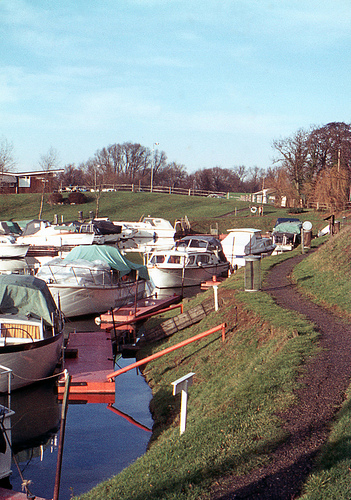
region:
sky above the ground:
[143, 13, 231, 85]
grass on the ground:
[208, 368, 263, 418]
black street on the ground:
[274, 393, 343, 437]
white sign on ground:
[156, 364, 212, 430]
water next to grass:
[93, 436, 121, 453]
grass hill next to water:
[132, 445, 181, 483]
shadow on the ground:
[237, 418, 302, 477]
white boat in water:
[156, 236, 224, 290]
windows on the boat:
[149, 252, 193, 274]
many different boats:
[8, 194, 227, 318]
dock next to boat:
[66, 327, 114, 400]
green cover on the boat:
[58, 238, 151, 292]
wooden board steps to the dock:
[171, 291, 254, 334]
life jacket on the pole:
[246, 200, 262, 215]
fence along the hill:
[113, 175, 346, 215]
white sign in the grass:
[164, 367, 194, 441]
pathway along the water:
[250, 248, 347, 489]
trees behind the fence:
[93, 145, 349, 202]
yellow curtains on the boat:
[7, 313, 43, 340]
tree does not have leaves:
[93, 168, 127, 206]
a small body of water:
[2, 219, 305, 497]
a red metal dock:
[59, 297, 229, 395]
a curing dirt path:
[209, 241, 345, 497]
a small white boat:
[0, 283, 68, 402]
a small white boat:
[41, 244, 148, 311]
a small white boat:
[144, 235, 232, 292]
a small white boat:
[221, 223, 270, 265]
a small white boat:
[113, 210, 174, 236]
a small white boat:
[20, 222, 97, 250]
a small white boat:
[0, 233, 28, 259]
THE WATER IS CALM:
[0, 300, 161, 499]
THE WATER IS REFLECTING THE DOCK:
[24, 337, 150, 472]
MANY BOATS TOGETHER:
[0, 214, 314, 498]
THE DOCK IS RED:
[52, 287, 230, 403]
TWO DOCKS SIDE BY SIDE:
[54, 285, 232, 396]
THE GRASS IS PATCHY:
[2, 191, 350, 498]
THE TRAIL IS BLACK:
[180, 243, 349, 498]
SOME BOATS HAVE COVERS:
[5, 238, 134, 323]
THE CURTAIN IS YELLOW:
[0, 321, 41, 337]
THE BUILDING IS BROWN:
[0, 158, 68, 194]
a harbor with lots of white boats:
[0, 96, 347, 494]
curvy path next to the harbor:
[254, 237, 343, 498]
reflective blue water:
[23, 388, 153, 486]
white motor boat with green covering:
[36, 242, 148, 312]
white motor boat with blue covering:
[147, 227, 228, 280]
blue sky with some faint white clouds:
[2, 7, 349, 165]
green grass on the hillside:
[3, 192, 228, 217]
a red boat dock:
[63, 315, 126, 407]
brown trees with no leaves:
[270, 111, 349, 216]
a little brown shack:
[4, 160, 67, 194]